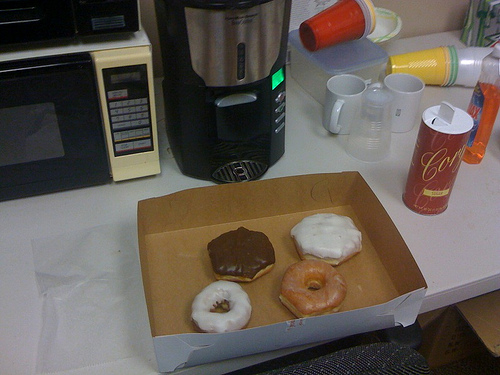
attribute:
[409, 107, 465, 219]
canister — creamer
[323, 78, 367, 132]
mug — white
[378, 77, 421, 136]
mug — white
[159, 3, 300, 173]
coffee pot — black, steel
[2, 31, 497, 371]
counter — white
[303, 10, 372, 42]
plastic cup — red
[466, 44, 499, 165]
dish soap bottle — orange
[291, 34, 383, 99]
tupperware bowl — white